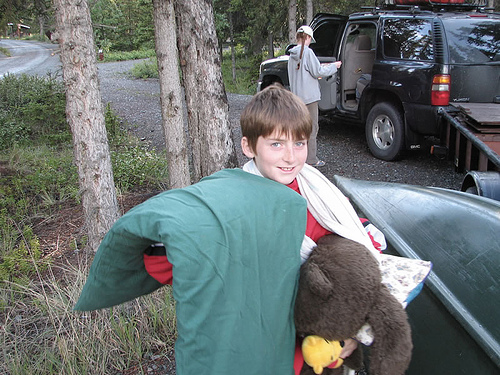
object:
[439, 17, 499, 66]
windows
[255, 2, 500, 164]
van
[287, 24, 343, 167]
girl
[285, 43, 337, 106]
sweater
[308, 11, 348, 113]
door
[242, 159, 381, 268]
sheet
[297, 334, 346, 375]
pooh bear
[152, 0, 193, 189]
bark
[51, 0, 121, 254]
cluttered trees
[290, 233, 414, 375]
bear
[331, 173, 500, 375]
boat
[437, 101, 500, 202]
trailer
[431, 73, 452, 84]
lights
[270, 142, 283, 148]
blue eyes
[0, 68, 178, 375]
grass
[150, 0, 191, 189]
tree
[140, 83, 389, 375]
boy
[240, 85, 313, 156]
hair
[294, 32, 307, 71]
braided hair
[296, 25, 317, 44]
hat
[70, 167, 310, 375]
pillow